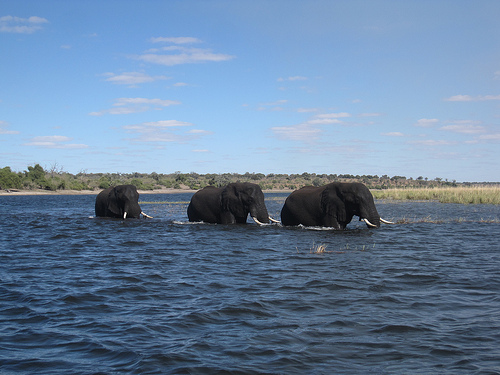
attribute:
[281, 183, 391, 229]
elephant — big, walking, first, in the middle, black, grey, gray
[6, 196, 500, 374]
water — calm, blue, shallow, brown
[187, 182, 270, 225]
elephant — walking, black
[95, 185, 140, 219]
elephant — small, walking, last, black, gray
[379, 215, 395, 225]
tusk — white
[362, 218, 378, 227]
tusk — white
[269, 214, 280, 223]
tusk — white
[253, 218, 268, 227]
tusk — white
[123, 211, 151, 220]
tusks — white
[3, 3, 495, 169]
sky — cloudy, blue, bright, clear, mostly clear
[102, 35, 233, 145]
clouds — thin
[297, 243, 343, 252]
grass — growing, green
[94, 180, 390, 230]
elephants — crossing